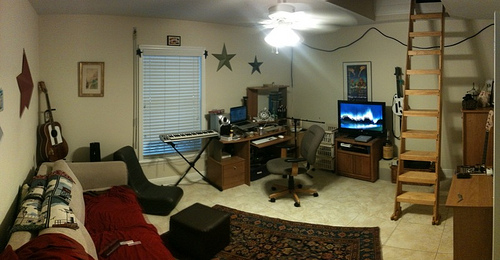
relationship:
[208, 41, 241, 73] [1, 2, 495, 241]
star on wall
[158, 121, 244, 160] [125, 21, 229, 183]
keyboard on window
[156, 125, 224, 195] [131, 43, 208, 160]
piano next to window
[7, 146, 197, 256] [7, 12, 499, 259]
furniture in room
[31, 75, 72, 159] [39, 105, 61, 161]
guitar on stand